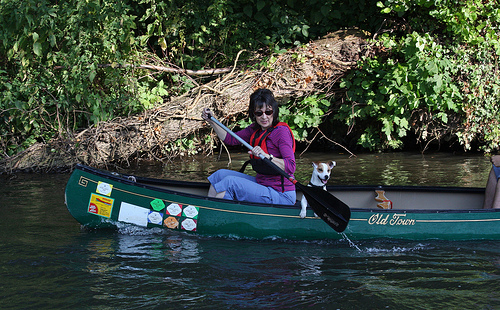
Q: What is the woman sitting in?
A: A canoe.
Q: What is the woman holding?
A: A paddle.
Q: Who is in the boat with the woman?
A: A dog.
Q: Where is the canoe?
A: In the water.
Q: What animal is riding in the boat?
A: Dog.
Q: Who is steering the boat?
A: The woman.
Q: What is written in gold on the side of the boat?
A: Old Town.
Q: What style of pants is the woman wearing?
A: Capris.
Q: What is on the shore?
A: A fallen tree.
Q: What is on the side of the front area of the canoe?
A: Stickers.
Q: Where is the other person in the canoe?
A: At the back.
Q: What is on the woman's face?
A: Sunglasses.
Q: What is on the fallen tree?
A: Leaves.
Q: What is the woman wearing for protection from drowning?
A: Life jacket.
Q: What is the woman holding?
A: Paddle.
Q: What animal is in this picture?
A: Dog.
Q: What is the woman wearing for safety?
A: Vest.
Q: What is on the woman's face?
A: Glasses.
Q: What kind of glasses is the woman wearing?
A: Sun.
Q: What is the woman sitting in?
A: Canoe.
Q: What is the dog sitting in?
A: Canoe.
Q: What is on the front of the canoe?
A: Stickers.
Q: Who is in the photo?
A: A woman.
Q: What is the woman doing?
A: Rowing.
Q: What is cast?
A: Reflection.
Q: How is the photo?
A: Clear.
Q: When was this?
A: Daytime.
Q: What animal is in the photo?
A: Dog.